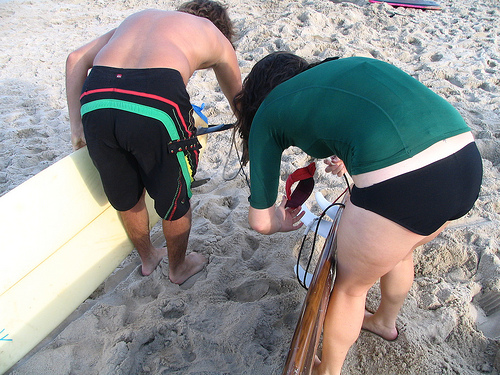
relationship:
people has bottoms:
[229, 50, 483, 374] [338, 135, 489, 239]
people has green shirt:
[229, 50, 483, 374] [241, 51, 479, 217]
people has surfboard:
[229, 50, 483, 374] [288, 184, 355, 373]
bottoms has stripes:
[80, 59, 206, 223] [73, 84, 204, 200]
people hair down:
[229, 50, 483, 374] [227, 46, 344, 175]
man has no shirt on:
[54, 2, 249, 289] [85, 7, 230, 70]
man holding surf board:
[54, 2, 249, 289] [1, 142, 128, 373]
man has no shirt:
[54, 2, 249, 289] [85, 7, 230, 70]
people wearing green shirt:
[229, 50, 483, 374] [241, 51, 479, 217]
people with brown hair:
[229, 50, 483, 374] [227, 46, 344, 175]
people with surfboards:
[56, 1, 487, 373] [0, 235, 325, 374]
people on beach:
[56, 1, 487, 373] [2, 4, 500, 375]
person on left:
[54, 2, 249, 289] [2, 5, 56, 371]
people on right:
[229, 50, 483, 374] [478, 1, 500, 373]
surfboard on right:
[288, 184, 355, 373] [478, 1, 500, 373]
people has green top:
[229, 50, 483, 374] [241, 51, 479, 217]